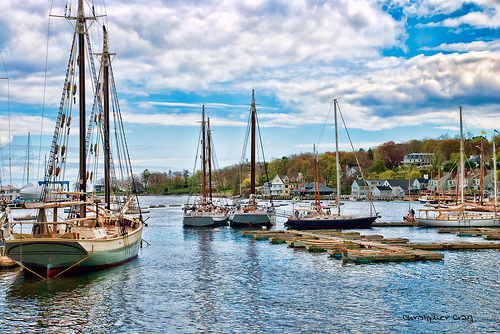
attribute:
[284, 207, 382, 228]
boat — dark 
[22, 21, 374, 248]
boat — boat masts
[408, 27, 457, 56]
sky — blue 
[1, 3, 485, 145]
clouds — white , puffy 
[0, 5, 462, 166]
sky — blue 